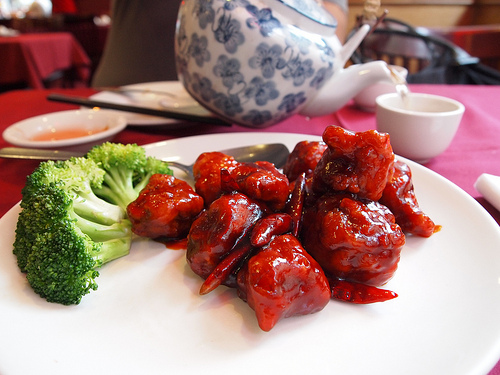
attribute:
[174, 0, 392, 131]
tea pot — blue, white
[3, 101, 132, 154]
bowl — small white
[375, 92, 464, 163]
teacup — white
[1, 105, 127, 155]
dish — white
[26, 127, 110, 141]
sauce — yellow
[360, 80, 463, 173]
cup — white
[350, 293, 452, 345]
plate — white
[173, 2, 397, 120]
tea pot — blue ceramic tea, white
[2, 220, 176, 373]
plate — white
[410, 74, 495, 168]
tablecloth — pink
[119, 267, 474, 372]
plate — white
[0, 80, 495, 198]
tablecloth — red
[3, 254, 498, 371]
plate — circular white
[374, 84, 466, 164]
tea cup — round white tea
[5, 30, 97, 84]
tablecloth — red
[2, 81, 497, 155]
table — restaurant 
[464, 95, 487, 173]
tablecloth — red 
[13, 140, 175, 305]
broccoli — green, pieces 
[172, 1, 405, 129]
teapot — floral, blue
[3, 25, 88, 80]
table cloth — dark, red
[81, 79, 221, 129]
plate — small white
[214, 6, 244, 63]
flower — blue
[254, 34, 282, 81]
flower — blue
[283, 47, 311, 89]
flower — blue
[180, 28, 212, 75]
flower — blue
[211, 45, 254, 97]
flower — blue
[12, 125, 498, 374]
plate — white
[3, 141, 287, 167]
silver spoon — silver 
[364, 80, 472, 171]
tea cup — white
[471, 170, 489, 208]
napkin — white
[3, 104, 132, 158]
dish — small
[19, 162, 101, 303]
broccoli head — green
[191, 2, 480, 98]
kettle — tea, blue, white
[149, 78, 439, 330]
chicken — Orange 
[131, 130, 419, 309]
food — red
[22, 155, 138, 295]
trees — Two green broccoli 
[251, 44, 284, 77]
floral — Blue 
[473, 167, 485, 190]
napkin — white , Edge 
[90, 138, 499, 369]
plate — white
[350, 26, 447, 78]
chair — wooden